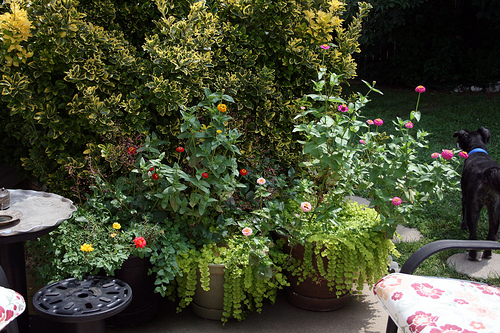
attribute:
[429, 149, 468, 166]
flowers — pink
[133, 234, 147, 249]
flower — red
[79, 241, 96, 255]
flower — yellow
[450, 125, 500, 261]
dog — black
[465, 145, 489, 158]
collar — blue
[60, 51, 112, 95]
leaves — green, yellow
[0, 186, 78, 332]
table — black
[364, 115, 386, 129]
flowers — pink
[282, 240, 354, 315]
pot — brown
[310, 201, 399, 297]
plant — green